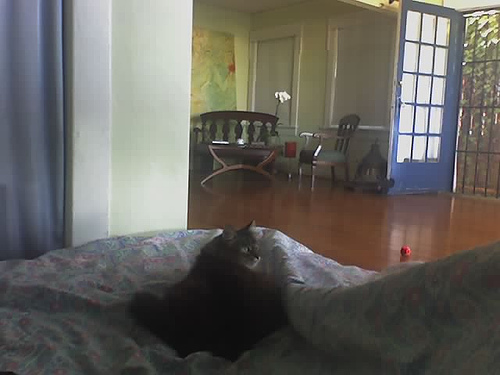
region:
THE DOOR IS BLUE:
[380, 0, 463, 200]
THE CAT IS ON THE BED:
[126, 214, 303, 372]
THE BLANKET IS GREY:
[0, 217, 499, 373]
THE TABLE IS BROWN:
[198, 136, 295, 191]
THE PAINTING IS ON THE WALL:
[187, 24, 242, 125]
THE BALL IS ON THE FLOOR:
[401, 245, 418, 262]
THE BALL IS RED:
[398, 240, 416, 263]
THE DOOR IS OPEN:
[389, 0, 498, 197]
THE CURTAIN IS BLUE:
[0, 0, 70, 260]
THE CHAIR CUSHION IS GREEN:
[297, 147, 344, 170]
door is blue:
[387, 1, 457, 263]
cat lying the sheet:
[121, 197, 265, 363]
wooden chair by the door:
[331, 109, 361, 191]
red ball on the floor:
[377, 221, 427, 266]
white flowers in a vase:
[258, 71, 287, 155]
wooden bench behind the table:
[203, 111, 280, 158]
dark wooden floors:
[305, 198, 477, 264]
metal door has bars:
[442, 36, 498, 198]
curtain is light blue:
[2, 18, 90, 246]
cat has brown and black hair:
[179, 217, 281, 365]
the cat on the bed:
[125, 216, 291, 352]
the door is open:
[388, 0, 458, 202]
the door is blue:
[385, 4, 460, 194]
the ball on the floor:
[396, 237, 420, 258]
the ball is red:
[397, 240, 414, 260]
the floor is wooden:
[282, 198, 388, 253]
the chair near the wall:
[296, 107, 371, 189]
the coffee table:
[191, 131, 292, 186]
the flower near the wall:
[256, 79, 305, 136]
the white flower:
[256, 83, 294, 104]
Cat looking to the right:
[128, 216, 288, 359]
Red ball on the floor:
[396, 240, 411, 258]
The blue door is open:
[386, 0, 466, 190]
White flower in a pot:
[261, 86, 291, 146]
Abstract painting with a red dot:
[188, 18, 240, 105]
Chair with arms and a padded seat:
[296, 110, 359, 190]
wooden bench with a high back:
[190, 105, 281, 153]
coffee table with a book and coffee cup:
[190, 136, 283, 186]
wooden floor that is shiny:
[293, 196, 434, 236]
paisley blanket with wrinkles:
[7, 264, 89, 362]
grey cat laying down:
[158, 203, 296, 358]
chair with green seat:
[301, 108, 376, 188]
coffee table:
[200, 131, 298, 193]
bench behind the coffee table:
[203, 97, 285, 168]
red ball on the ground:
[390, 237, 435, 272]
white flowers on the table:
[268, 84, 294, 149]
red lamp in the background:
[281, 132, 306, 196]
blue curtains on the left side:
[3, 12, 101, 288]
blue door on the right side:
[382, 0, 459, 208]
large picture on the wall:
[194, 24, 250, 124]